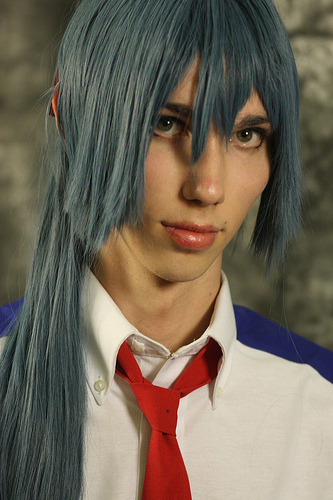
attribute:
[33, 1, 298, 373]
person — androgynous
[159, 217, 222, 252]
lips — full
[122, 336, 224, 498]
neck tie — red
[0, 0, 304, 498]
hair — black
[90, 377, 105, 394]
button — small, clear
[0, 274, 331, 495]
shirt — blue, white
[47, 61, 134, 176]
hair — bluish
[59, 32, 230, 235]
man — young